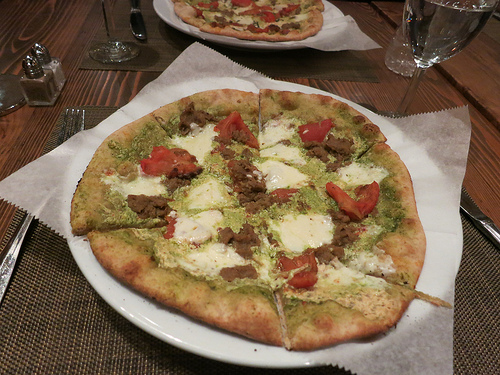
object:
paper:
[5, 152, 71, 244]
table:
[0, 0, 500, 375]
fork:
[0, 108, 85, 307]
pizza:
[69, 87, 425, 351]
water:
[400, 0, 496, 70]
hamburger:
[203, 134, 304, 222]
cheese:
[177, 111, 207, 151]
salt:
[30, 42, 66, 89]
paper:
[138, 62, 202, 106]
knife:
[407, 124, 499, 277]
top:
[48, 99, 101, 153]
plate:
[63, 76, 465, 367]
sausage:
[125, 192, 173, 220]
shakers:
[16, 42, 68, 107]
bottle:
[374, 0, 499, 119]